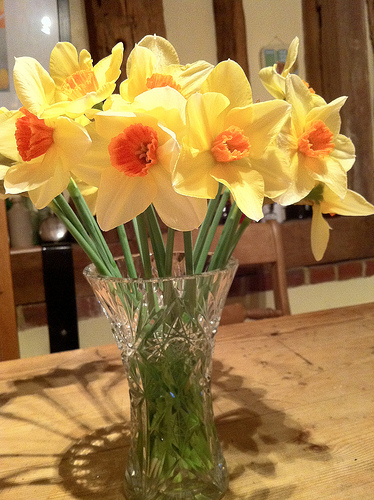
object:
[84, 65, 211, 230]
flower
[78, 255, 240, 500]
vase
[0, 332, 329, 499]
shadow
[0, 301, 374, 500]
table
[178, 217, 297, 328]
chair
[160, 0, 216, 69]
wall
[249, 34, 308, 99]
art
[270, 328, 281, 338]
hole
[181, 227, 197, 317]
stem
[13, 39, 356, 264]
boquet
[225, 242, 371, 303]
brick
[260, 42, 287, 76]
picture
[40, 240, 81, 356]
belt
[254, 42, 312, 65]
frame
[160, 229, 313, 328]
object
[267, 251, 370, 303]
trim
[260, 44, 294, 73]
plaque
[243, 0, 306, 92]
wall